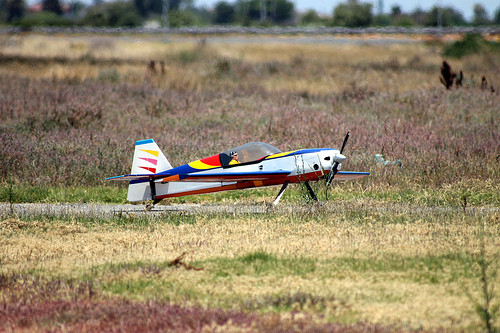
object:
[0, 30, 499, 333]
dry grass